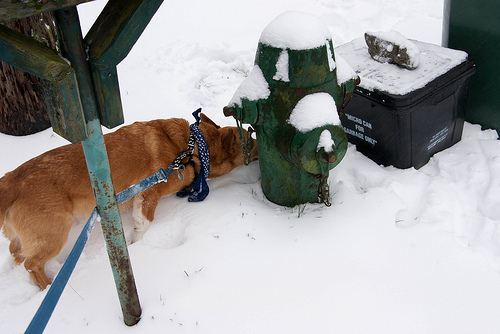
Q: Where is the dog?
A: On the snow.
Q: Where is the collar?
A: On the dog.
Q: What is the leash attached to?
A: The collar.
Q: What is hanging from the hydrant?
A: Chains.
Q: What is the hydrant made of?
A: Metal.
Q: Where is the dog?
A: On the snow.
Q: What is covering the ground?
A: White snow.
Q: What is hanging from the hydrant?
A: Chains.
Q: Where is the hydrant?
A: Next to the dog.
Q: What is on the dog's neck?
A: A collar.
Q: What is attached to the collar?
A: A leash.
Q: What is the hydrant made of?
A: Metal.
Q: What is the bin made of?
A: Plastic.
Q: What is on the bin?
A: A rock.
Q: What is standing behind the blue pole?
A: The dog.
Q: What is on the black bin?
A: White print.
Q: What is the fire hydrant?
A: Green.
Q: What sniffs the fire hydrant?
A: The dog.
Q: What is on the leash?
A: The dog.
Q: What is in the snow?
A: The dog.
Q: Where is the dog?
A: In the snow.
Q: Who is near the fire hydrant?
A: The dog.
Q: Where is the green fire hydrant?
A: Under the snow.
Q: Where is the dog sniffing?
A: Near the fire hydrant and the trash bin.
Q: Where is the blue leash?
A: Attached to the dog.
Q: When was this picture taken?
A: After it snowed.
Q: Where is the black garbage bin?
A: Next to the fire hydrant.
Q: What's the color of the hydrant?
A: Green.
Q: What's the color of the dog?
A: Brown.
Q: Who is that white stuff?
A: Snow.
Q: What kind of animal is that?
A: Dog.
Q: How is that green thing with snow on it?
A: Fire hydrant.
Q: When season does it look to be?
A: Winter.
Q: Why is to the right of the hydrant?
A: Black box.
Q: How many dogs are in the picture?
A: One.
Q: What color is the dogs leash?
A: Blue.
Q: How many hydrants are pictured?
A: One.